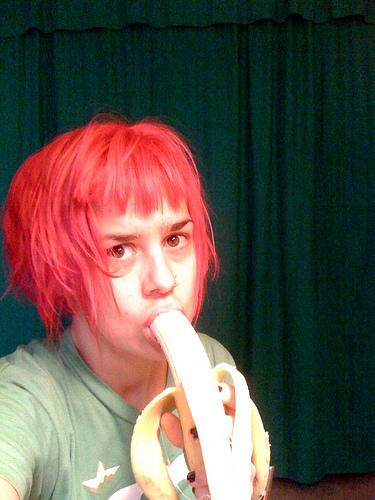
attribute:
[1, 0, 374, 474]
drapes — green, dark green, large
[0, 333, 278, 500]
shirt — green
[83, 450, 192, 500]
logo — white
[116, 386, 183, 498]
peel — yellow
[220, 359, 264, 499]
peel — yellow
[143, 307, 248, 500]
banana — peel, ripe, large, yellow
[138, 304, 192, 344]
mouth — pink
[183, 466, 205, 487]
nail — dark, paint, painted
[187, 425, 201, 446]
nail — dark, paint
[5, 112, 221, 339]
hair — orange, red, bright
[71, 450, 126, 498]
star — yellow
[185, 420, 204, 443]
fingernail — painted